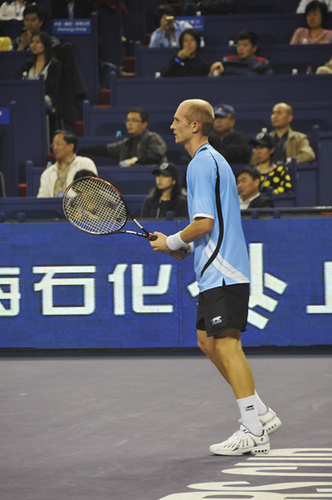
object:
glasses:
[125, 118, 143, 123]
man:
[149, 98, 282, 458]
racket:
[62, 176, 157, 242]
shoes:
[209, 407, 283, 456]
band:
[166, 231, 189, 251]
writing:
[0, 242, 332, 331]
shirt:
[255, 161, 292, 194]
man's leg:
[196, 334, 266, 430]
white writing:
[159, 447, 332, 500]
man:
[0, 0, 332, 220]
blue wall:
[0, 220, 332, 348]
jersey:
[186, 142, 252, 293]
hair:
[184, 99, 215, 137]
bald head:
[170, 99, 215, 144]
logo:
[211, 316, 222, 326]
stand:
[1, 216, 330, 357]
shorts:
[196, 283, 250, 337]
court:
[0, 352, 332, 500]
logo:
[244, 404, 255, 411]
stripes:
[205, 232, 250, 283]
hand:
[150, 231, 188, 260]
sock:
[236, 389, 267, 436]